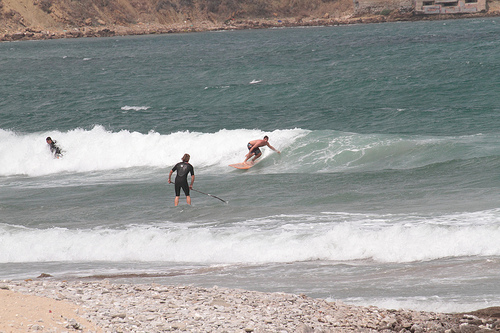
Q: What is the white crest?
A: Wave.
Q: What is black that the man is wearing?
A: Wetsuit.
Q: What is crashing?
A: Waves.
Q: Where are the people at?
A: Water.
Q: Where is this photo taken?
A: Beach.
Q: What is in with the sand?
A: Rocks.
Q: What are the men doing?
A: Surfing.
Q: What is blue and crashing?
A: Water.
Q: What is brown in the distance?
A: Dirt.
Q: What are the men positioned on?
A: Waves.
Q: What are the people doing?
A: Surfing.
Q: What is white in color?
A: The waves.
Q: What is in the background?
A: Cliffs.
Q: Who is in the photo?
A: Surfers.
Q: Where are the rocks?
A: On the sand.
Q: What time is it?
A: Afternoon.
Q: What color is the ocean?
A: Blue.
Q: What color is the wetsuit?
A: Black.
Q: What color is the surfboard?
A: Orange.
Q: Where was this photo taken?
A: At a beach.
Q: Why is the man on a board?
A: He is surfing.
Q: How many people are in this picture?
A: Three.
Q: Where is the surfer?
A: In the water.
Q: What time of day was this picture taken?
A: Day time.